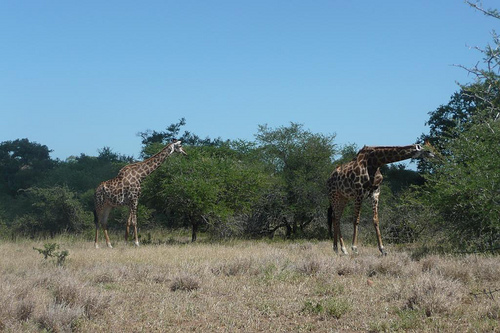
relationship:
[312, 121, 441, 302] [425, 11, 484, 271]
giraffe eating from a tree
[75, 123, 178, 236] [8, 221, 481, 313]
giraffe in field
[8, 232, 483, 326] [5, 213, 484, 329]
grass in field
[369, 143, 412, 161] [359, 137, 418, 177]
shadow on neck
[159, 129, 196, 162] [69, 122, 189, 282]
head on giraffe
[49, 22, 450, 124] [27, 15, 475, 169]
clouds in sky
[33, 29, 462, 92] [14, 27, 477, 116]
clouds in sky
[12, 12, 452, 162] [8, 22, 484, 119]
clouds in sky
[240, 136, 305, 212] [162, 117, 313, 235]
leaves on tree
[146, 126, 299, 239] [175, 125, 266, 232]
leaves on tree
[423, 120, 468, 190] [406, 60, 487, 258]
leaves on tree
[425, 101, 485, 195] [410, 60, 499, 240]
leaves on tree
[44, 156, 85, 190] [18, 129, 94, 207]
leaves on tree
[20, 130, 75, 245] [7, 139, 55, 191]
leaves on tree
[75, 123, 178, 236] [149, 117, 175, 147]
giraffe with head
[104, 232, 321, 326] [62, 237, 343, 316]
grass in field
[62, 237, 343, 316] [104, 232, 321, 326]
field with grass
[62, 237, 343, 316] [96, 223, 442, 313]
field of grass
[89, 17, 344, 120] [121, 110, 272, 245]
sky aboce trees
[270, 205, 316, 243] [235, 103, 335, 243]
trunks under trees